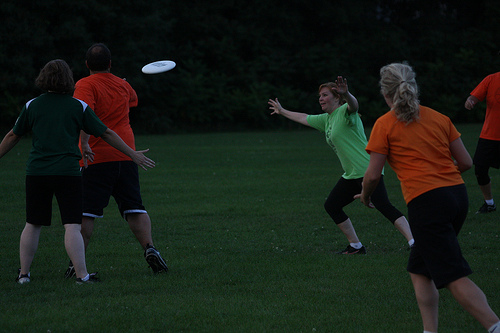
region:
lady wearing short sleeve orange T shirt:
[71, 59, 156, 184]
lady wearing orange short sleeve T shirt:
[367, 92, 484, 240]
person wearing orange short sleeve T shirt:
[460, 56, 497, 153]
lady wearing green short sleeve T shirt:
[294, 89, 389, 193]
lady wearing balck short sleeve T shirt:
[20, 85, 93, 202]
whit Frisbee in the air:
[127, 29, 190, 125]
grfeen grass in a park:
[183, 145, 345, 310]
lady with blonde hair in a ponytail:
[357, 48, 457, 130]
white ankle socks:
[332, 227, 429, 263]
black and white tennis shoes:
[15, 254, 95, 301]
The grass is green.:
[1, 127, 498, 332]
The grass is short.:
[0, 135, 499, 329]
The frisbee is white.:
[136, 55, 179, 77]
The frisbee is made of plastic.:
[137, 55, 179, 77]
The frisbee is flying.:
[133, 53, 178, 75]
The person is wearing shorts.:
[396, 180, 482, 291]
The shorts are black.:
[401, 180, 484, 290]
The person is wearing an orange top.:
[363, 102, 474, 206]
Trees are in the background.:
[1, 0, 498, 132]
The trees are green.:
[0, 1, 498, 137]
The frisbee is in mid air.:
[138, 55, 178, 77]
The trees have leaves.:
[0, 0, 498, 140]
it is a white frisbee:
[136, 52, 183, 77]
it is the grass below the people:
[206, 171, 248, 241]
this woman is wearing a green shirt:
[326, 115, 350, 157]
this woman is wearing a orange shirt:
[386, 129, 446, 179]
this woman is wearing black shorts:
[416, 203, 457, 264]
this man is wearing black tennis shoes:
[144, 240, 168, 270]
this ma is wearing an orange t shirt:
[478, 71, 496, 130]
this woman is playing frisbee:
[277, 84, 388, 191]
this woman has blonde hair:
[380, 63, 423, 108]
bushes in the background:
[203, 45, 253, 91]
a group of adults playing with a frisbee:
[6, 5, 495, 327]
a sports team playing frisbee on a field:
[3, 5, 497, 327]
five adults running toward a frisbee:
[16, 35, 498, 317]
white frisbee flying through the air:
[139, 55, 179, 76]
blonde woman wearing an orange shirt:
[372, 61, 478, 331]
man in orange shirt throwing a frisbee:
[67, 42, 159, 281]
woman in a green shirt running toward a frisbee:
[267, 70, 382, 257]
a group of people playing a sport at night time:
[4, 6, 496, 324]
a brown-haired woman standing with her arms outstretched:
[7, 56, 103, 291]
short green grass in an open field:
[0, 280, 413, 330]